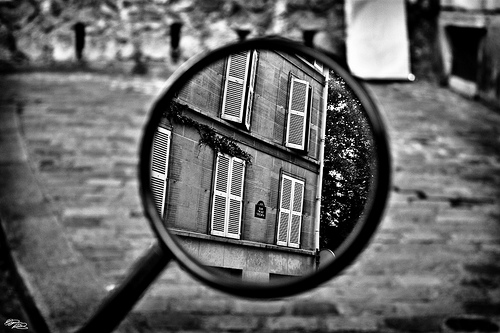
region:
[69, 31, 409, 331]
rear view mirror reflects apartment building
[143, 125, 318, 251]
closed shuttered windows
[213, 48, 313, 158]
slightly open shuttered windows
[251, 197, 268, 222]
apartment, or triplex, number plate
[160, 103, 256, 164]
plants vining across side of building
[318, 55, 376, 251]
leaved tree/s behind building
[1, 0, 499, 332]
background behind mirror blurred out in photoshop, a bit heavyhandedly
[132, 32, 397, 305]
dark round mirror frame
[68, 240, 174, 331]
somewhat blurry mirror arm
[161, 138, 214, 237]
the imprint of shutter against wall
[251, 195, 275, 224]
a sign on a building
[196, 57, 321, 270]
four windows with shutters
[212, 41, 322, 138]
two windows with open shutters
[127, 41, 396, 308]
a rear view mirror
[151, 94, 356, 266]
reflection in a mirror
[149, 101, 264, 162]
vines growing on a building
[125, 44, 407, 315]
a round mirror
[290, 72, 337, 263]
a gutter spout on a building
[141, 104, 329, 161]
trim on a building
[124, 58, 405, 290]
a black rear view mirror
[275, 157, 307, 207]
part of a window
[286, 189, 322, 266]
part of a mirror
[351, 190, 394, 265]
edge of a mirror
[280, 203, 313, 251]
part of a mirror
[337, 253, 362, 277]
edge of a mirror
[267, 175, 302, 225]
part of a mirror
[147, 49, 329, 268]
a building reflection in the mirror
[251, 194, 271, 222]
a sign on the building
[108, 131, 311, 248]
the lower windows are closed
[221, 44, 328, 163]
the upper windows are cracked open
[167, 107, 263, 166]
a plant growing over the window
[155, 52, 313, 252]
the shutters are white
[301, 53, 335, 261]
a pole up the side of the building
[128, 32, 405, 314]
the mirror is round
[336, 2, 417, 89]
a white object behind the mirror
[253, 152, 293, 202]
part of a mirror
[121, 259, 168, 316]
part of a handle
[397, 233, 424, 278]
part of a walkl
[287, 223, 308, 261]
part of a mirror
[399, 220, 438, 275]
part fo a wall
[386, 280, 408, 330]
part fo a wall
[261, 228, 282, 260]
part of a mirror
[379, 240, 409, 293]
part fo a wall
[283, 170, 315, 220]
part of a mirror